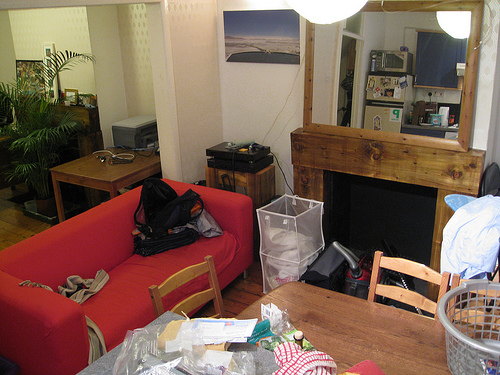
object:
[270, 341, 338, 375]
was cloth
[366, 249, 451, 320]
chair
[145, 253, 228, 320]
chair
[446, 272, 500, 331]
chair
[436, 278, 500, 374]
laundry basket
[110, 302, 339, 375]
clutter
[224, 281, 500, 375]
table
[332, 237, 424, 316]
vacume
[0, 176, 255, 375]
couch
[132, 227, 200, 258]
stuff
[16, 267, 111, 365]
stuff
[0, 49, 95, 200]
plant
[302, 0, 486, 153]
mirror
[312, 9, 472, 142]
reflection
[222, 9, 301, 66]
picture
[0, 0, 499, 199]
wall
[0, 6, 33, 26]
corner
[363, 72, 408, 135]
refrigerator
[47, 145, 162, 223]
table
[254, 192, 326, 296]
hamper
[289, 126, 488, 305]
fireplace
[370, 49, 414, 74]
microwave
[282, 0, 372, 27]
light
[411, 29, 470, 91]
window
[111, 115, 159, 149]
printer